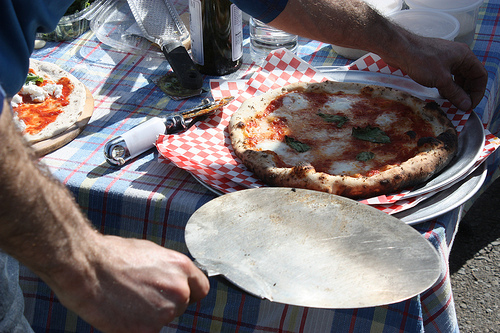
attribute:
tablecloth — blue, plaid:
[6, 2, 495, 331]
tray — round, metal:
[182, 184, 445, 309]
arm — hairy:
[0, 112, 90, 262]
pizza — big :
[210, 74, 472, 212]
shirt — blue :
[1, 2, 286, 127]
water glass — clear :
[246, 18, 299, 54]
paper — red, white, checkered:
[153, 36, 498, 221]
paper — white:
[154, 115, 247, 189]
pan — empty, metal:
[180, 182, 447, 313]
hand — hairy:
[19, 181, 214, 328]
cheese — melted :
[277, 82, 317, 120]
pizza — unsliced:
[221, 67, 462, 197]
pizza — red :
[240, 73, 477, 205]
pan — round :
[224, 70, 484, 199]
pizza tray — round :
[449, 153, 474, 178]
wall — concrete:
[437, 230, 489, 300]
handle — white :
[102, 106, 187, 166]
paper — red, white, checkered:
[159, 47, 473, 207]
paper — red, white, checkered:
[211, 49, 484, 221]